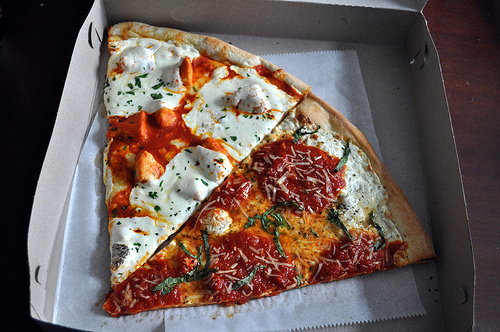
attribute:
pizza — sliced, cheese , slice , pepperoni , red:
[102, 28, 430, 305]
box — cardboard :
[26, 8, 482, 327]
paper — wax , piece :
[304, 62, 362, 102]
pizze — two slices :
[107, 20, 434, 319]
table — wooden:
[440, 20, 483, 329]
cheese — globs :
[118, 43, 190, 103]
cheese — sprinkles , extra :
[269, 151, 319, 194]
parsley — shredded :
[255, 209, 291, 243]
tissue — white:
[65, 254, 99, 312]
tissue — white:
[63, 277, 94, 312]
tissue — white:
[61, 272, 112, 322]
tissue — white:
[64, 270, 93, 310]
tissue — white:
[66, 271, 104, 326]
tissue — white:
[65, 243, 100, 310]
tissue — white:
[68, 255, 82, 304]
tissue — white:
[70, 241, 82, 306]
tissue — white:
[309, 50, 362, 101]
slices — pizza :
[111, 12, 310, 286]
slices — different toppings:
[97, 22, 427, 303]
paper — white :
[306, 53, 377, 90]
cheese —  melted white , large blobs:
[204, 84, 269, 132]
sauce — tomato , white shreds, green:
[285, 141, 333, 214]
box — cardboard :
[372, 33, 452, 157]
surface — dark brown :
[460, 77, 481, 148]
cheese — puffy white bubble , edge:
[197, 98, 248, 135]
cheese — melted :
[204, 81, 259, 147]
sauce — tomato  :
[281, 155, 326, 207]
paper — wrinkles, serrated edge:
[66, 234, 100, 309]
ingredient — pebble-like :
[192, 247, 283, 278]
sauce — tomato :
[285, 152, 325, 201]